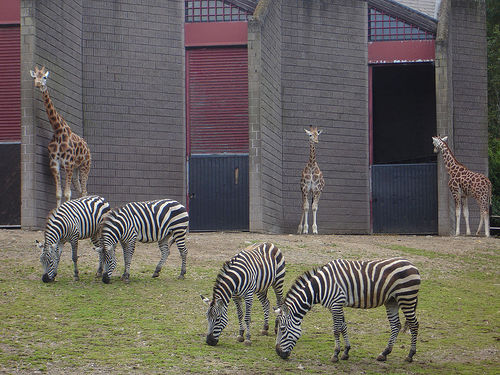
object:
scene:
[0, 0, 499, 372]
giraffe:
[430, 133, 497, 237]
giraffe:
[295, 127, 327, 235]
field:
[1, 228, 499, 373]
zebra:
[270, 255, 422, 361]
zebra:
[203, 241, 287, 347]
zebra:
[93, 197, 191, 284]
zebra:
[39, 194, 116, 283]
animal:
[97, 197, 192, 284]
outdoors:
[0, 0, 499, 373]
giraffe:
[28, 64, 93, 209]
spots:
[461, 166, 465, 172]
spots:
[313, 175, 319, 182]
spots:
[73, 142, 80, 149]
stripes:
[391, 279, 421, 292]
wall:
[280, 0, 368, 234]